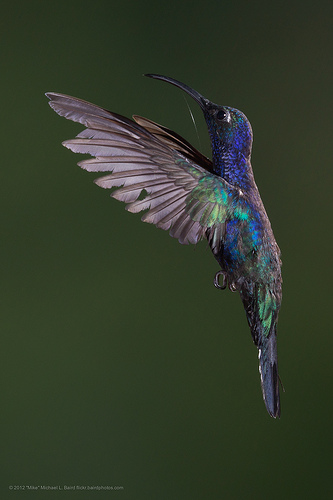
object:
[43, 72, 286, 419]
hummingbird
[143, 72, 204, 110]
beak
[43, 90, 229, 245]
wing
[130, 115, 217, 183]
wing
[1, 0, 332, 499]
background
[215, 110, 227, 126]
eye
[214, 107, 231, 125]
lining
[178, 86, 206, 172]
spider web strand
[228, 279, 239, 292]
right foot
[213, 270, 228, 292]
left foot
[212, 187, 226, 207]
feather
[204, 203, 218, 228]
feather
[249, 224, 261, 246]
feather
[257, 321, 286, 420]
tail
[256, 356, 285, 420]
tip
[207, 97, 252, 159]
head